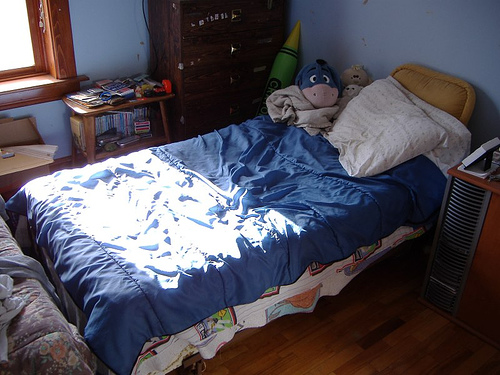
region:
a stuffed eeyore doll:
[282, 50, 342, 113]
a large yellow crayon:
[257, 13, 301, 135]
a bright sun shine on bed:
[37, 178, 277, 290]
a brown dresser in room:
[157, 8, 265, 115]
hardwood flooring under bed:
[316, 321, 442, 366]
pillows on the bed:
[366, 63, 454, 191]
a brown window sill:
[0, 14, 77, 104]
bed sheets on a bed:
[161, 302, 421, 349]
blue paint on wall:
[326, 7, 469, 64]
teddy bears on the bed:
[300, 58, 371, 124]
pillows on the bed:
[341, 55, 496, 151]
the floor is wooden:
[197, 289, 491, 374]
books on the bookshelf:
[87, 110, 172, 147]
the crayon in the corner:
[232, 18, 308, 103]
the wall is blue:
[295, 5, 497, 72]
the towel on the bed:
[257, 88, 324, 135]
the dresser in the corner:
[149, 3, 271, 115]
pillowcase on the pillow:
[335, 77, 410, 188]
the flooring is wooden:
[291, 342, 395, 367]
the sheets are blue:
[124, 301, 164, 327]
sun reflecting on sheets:
[113, 203, 235, 280]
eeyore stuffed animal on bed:
[297, 67, 347, 101]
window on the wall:
[9, 3, 71, 83]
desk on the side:
[66, 88, 180, 150]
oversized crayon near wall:
[269, 9, 298, 88]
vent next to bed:
[439, 171, 469, 268]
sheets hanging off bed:
[195, 312, 256, 346]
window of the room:
[4, 0, 81, 80]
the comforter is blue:
[89, 299, 144, 329]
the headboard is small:
[394, 63, 478, 117]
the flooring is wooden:
[340, 285, 439, 374]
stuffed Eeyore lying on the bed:
[288, 54, 344, 116]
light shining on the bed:
[37, 143, 279, 290]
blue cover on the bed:
[7, 114, 422, 366]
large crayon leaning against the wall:
[256, 20, 313, 123]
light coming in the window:
[1, 0, 56, 85]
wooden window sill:
[0, 68, 93, 113]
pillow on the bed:
[318, 73, 450, 192]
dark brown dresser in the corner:
[143, 0, 300, 139]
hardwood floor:
[186, 273, 496, 374]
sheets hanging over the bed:
[130, 210, 420, 369]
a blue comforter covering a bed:
[83, 287, 145, 359]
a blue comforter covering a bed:
[146, 264, 192, 354]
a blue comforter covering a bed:
[234, 213, 288, 306]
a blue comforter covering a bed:
[290, 198, 335, 281]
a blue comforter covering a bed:
[333, 177, 379, 263]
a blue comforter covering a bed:
[21, 173, 88, 253]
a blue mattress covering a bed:
[199, 250, 249, 322]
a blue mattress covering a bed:
[241, 225, 281, 310]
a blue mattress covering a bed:
[283, 219, 319, 287]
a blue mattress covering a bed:
[6, 169, 96, 238]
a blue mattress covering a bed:
[80, 148, 179, 214]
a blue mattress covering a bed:
[171, 125, 244, 197]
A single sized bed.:
[55, 61, 456, 366]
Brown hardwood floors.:
[121, 270, 496, 373]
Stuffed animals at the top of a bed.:
[282, 54, 378, 121]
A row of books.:
[67, 107, 162, 147]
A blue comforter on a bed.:
[11, 123, 451, 365]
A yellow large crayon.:
[254, 23, 308, 123]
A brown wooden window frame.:
[0, 0, 89, 122]